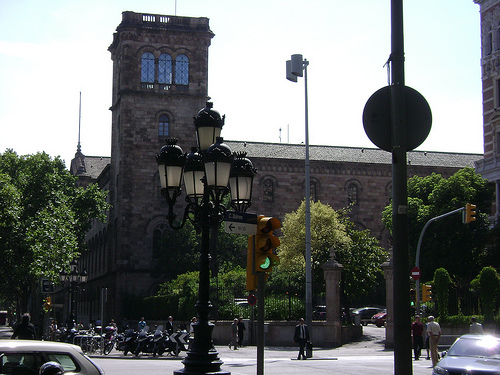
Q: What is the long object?
A: Light pole.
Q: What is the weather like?
A: Cloudy.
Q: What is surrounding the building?
A: Fence.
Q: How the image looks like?
A: Good.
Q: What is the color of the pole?
A: Black.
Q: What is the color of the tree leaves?
A: Green.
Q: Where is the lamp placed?
A: Side of road.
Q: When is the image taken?
A: When roads are busy.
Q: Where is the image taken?
A: Near to the church.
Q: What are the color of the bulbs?
A: White.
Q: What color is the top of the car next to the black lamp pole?
A: Grey.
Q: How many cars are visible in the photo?
A: Two.